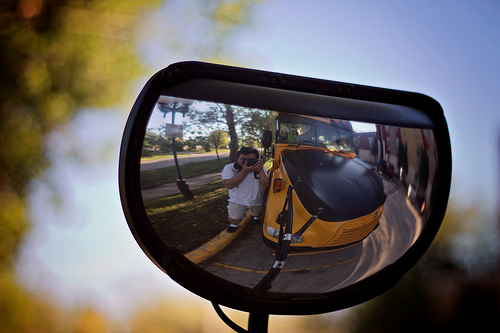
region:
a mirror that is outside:
[148, 33, 393, 330]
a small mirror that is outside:
[87, 46, 492, 314]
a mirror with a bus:
[165, 81, 499, 307]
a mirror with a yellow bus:
[191, 67, 497, 285]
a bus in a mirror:
[226, 15, 486, 217]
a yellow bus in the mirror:
[255, 114, 401, 264]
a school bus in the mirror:
[219, 127, 456, 309]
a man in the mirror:
[205, 129, 335, 322]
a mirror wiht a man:
[210, 127, 332, 257]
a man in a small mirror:
[162, 77, 449, 302]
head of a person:
[233, 142, 259, 172]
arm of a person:
[228, 165, 256, 187]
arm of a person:
[252, 167, 270, 194]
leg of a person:
[218, 195, 254, 237]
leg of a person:
[246, 196, 273, 227]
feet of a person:
[226, 225, 242, 230]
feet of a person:
[254, 213, 269, 220]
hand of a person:
[245, 155, 262, 166]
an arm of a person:
[228, 167, 244, 188]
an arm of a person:
[255, 159, 285, 185]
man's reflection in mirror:
[218, 142, 270, 241]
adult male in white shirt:
[215, 143, 269, 233]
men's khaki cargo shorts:
[220, 195, 267, 225]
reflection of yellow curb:
[182, 210, 256, 267]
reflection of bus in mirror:
[257, 110, 392, 259]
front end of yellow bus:
[262, 142, 388, 259]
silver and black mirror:
[100, 55, 462, 320]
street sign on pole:
[160, 117, 186, 144]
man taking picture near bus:
[212, 138, 271, 235]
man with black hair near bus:
[210, 138, 278, 233]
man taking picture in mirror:
[114, 55, 458, 312]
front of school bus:
[263, 124, 378, 236]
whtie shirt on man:
[230, 166, 250, 200]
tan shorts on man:
[220, 194, 260, 224]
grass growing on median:
[165, 206, 215, 246]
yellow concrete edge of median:
[190, 223, 249, 258]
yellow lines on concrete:
[219, 260, 311, 284]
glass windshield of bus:
[267, 112, 363, 156]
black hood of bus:
[278, 140, 392, 211]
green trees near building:
[389, 134, 409, 181]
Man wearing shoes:
[225, 215, 267, 237]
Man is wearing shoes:
[226, 215, 265, 237]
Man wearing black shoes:
[224, 214, 269, 236]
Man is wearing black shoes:
[225, 212, 267, 237]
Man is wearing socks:
[229, 215, 268, 234]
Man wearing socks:
[228, 213, 265, 232]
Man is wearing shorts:
[225, 195, 274, 220]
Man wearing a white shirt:
[218, 155, 268, 210]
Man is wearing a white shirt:
[220, 161, 271, 206]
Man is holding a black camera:
[236, 154, 266, 171]